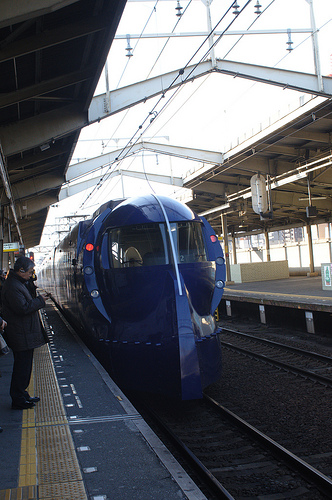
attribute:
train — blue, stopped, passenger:
[68, 203, 232, 381]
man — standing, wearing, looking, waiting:
[17, 250, 54, 362]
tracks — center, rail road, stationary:
[160, 393, 294, 489]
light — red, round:
[72, 229, 101, 259]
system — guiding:
[28, 217, 170, 320]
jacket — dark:
[10, 286, 55, 338]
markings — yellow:
[13, 399, 58, 475]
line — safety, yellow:
[14, 422, 58, 469]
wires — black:
[115, 38, 205, 108]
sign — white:
[233, 165, 267, 205]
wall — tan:
[233, 236, 265, 277]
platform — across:
[50, 329, 149, 500]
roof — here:
[5, 23, 121, 170]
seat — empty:
[116, 229, 190, 284]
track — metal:
[222, 403, 309, 448]